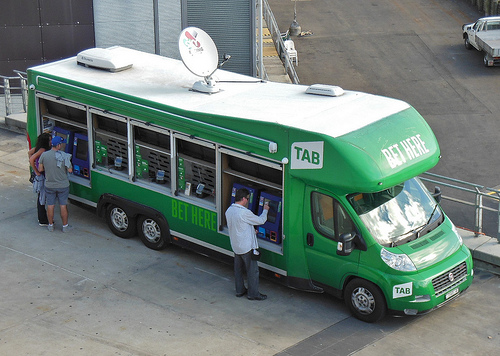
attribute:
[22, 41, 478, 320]
truck — green, white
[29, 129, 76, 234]
people — together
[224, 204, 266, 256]
shirt — white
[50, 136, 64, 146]
hat — blue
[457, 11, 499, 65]
truck — white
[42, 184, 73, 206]
shorts — blue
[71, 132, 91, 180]
machine — blue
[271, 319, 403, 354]
line — grey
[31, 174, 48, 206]
shirt — blue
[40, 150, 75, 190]
shirt — green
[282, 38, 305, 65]
chairs — white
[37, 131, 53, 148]
hair — brown